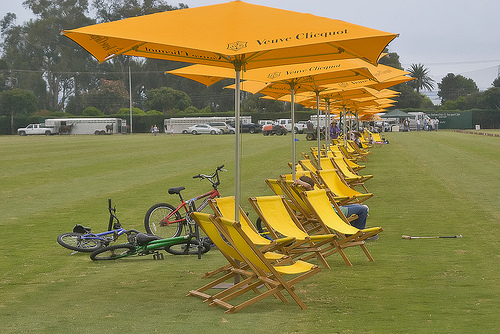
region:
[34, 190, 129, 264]
blue bike laying on ground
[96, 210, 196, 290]
green bike laying on ground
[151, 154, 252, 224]
red and black bike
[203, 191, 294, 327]
yellow and wooden chairs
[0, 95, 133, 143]
white truck and trailer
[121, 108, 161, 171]
people on the grass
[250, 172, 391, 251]
person sitting on a chair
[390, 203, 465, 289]
object laying on grass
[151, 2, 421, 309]
yellow chairs and umbrellas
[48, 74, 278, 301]
three bikes in grass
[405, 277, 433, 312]
part of a green ground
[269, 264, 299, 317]
part of a stand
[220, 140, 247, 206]
part of a post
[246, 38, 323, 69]
edge of an umbrella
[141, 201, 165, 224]
edge of a wheel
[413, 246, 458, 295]
part of a ground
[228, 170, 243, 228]
part of a post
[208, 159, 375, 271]
yellow chairs in field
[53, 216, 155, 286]
bikes on the ground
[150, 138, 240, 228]
red bike standing up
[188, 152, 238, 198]
handlebars of a bike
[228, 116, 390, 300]
many yellow chairs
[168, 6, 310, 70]
umbrellas over the chairs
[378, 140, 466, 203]
green grass next to field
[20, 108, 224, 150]
cars in the background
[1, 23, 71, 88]
trees in the distance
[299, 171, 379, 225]
person sitting in chair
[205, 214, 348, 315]
Lounge chair is yellow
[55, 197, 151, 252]
Blue bike on green grass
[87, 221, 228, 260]
Green bike on green grass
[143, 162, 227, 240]
Red bike on green grass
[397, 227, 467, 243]
Polo mallet on green grass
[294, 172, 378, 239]
Man sitting on yellow lounge chair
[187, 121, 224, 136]
Silver sedan is parked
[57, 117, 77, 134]
Brown horse by white truck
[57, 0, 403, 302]
Umbrella is large and yellow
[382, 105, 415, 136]
Umbrella is large and green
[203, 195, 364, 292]
Yellow chairs are on the field.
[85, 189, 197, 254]
Bicycles sitting on the ground at the park.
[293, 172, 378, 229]
A man is sitting in the folding chair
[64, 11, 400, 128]
The umbrellas are lined up in a row.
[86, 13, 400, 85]
The umbrellas are yellow.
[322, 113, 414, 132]
People staanding around in the parking lot.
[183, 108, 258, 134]
Cars parked behind the fence.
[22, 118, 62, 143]
A truck with horses parked behind the fence.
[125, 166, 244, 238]
a red bicycle behind the yellow chair.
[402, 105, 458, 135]
People standing around by the van.